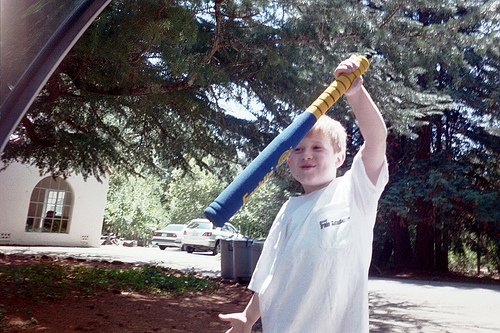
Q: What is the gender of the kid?
A: Male.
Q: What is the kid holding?
A: Bat.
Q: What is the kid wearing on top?
A: Shirt.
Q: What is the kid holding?
A: Bat.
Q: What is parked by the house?
A: Cars.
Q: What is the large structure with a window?
A: House.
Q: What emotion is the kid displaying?
A: Happyness.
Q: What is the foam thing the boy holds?
A: Bat.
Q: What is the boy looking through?
A: Eyes.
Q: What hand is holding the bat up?
A: Left hand.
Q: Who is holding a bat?
A: Boy.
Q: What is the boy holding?
A: A bat.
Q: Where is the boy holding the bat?
A: In the yard.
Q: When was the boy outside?
A: During daylight hours.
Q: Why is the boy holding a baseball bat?
A: He is playing baseball.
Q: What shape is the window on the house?
A: Arch-shaped.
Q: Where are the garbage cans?
A: Along the driveway.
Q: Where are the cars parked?
A: Near the house.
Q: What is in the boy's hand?
A: Bat.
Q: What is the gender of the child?
A: Male.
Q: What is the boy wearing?
A: A white shirt.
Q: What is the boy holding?
A: A baseball bat.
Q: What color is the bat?
A: Blue.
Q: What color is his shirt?
A: White.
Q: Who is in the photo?
A: A boy.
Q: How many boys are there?
A: One.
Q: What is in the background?
A: Trees.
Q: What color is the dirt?
A: Brown.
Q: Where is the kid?
A: In the yard.